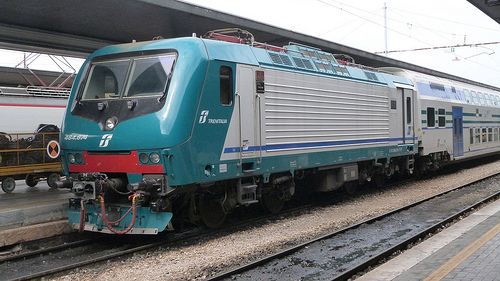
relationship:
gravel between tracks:
[192, 237, 276, 260] [90, 215, 403, 280]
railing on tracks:
[49, 30, 500, 240] [90, 215, 403, 280]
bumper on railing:
[68, 151, 169, 179] [49, 30, 500, 240]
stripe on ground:
[462, 235, 491, 262] [427, 231, 498, 270]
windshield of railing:
[68, 55, 193, 99] [49, 30, 500, 240]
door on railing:
[452, 84, 477, 161] [49, 30, 500, 240]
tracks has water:
[90, 215, 403, 280] [302, 231, 410, 253]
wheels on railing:
[195, 194, 294, 221] [49, 30, 500, 240]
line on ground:
[413, 208, 499, 271] [355, 199, 500, 281]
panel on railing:
[62, 154, 152, 176] [49, 30, 500, 240]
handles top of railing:
[218, 23, 327, 51] [49, 30, 500, 240]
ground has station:
[355, 199, 500, 281] [105, 13, 498, 253]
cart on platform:
[6, 136, 72, 171] [6, 177, 66, 218]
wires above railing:
[364, 13, 487, 58] [49, 30, 500, 240]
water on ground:
[302, 231, 410, 253] [427, 231, 498, 270]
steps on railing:
[236, 175, 261, 203] [49, 30, 500, 240]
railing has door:
[49, 30, 500, 240] [452, 84, 477, 161]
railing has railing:
[49, 30, 500, 240] [238, 97, 273, 169]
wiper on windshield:
[164, 64, 174, 92] [68, 55, 193, 99]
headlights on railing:
[60, 147, 165, 165] [49, 30, 500, 240]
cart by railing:
[6, 136, 72, 171] [49, 30, 500, 240]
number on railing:
[61, 126, 87, 142] [49, 30, 500, 240]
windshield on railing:
[68, 55, 193, 99] [49, 30, 500, 240]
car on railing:
[430, 83, 490, 164] [49, 30, 500, 240]